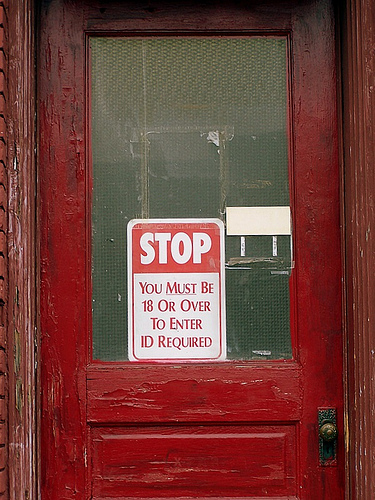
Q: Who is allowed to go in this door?
A: People who are 18 or over with an ID.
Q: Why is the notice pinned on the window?
A: To tell people who can and cannot go inside.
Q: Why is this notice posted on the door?
A: To let people know who can come in.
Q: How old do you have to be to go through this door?
A: 18 or over.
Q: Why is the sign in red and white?
A: To get people's attention.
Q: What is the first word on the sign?
A: Stop.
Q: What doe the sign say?
A: Stop.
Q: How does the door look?
A: Old.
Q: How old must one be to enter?
A: 18.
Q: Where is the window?
A: On the door.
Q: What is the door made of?
A: Wood.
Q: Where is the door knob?
A: On the red door.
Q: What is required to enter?
A: An ID.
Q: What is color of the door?
A: Red.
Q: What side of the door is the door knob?
A: Right.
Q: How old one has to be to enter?
A: 18 or over.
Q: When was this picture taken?
A: During the day.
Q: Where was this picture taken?
A: Outside a business.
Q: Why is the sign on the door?
A: To tell people the age to enter.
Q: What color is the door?
A: Red.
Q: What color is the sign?
A: Red and white.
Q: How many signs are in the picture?
A: One.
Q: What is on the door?
A: A door knob.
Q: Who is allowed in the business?
A: People 18 years of age and older.